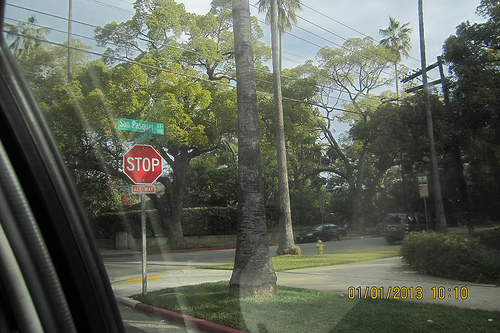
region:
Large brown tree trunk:
[210, 43, 274, 302]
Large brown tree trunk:
[415, 110, 453, 242]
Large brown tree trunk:
[335, 148, 364, 245]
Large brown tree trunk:
[267, 103, 302, 258]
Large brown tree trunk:
[161, 161, 196, 281]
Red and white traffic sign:
[118, 140, 159, 280]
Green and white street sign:
[103, 105, 178, 135]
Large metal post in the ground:
[122, 193, 152, 298]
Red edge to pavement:
[132, 297, 195, 328]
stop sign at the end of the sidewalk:
[111, 131, 172, 301]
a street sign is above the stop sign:
[112, 105, 167, 141]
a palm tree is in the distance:
[262, 1, 296, 252]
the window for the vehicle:
[27, 15, 474, 325]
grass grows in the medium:
[153, 279, 485, 329]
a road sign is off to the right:
[410, 168, 435, 226]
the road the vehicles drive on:
[103, 185, 477, 322]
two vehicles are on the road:
[293, 212, 434, 247]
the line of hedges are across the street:
[102, 202, 355, 243]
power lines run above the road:
[4, 0, 455, 130]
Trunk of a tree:
[271, 0, 299, 273]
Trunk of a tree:
[393, 47, 416, 247]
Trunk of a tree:
[350, 95, 376, 249]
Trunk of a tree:
[291, 136, 314, 232]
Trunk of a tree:
[169, 101, 202, 253]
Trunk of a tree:
[265, 5, 302, 264]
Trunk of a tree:
[288, 118, 317, 239]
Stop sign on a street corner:
[121, 143, 179, 315]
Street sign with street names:
[111, 107, 176, 182]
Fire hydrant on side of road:
[301, 225, 338, 263]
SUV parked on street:
[382, 173, 446, 263]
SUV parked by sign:
[384, 165, 443, 257]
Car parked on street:
[290, 214, 357, 247]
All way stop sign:
[113, 137, 172, 216]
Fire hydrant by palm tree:
[258, 0, 340, 267]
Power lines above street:
[301, 4, 462, 122]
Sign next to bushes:
[391, 169, 498, 288]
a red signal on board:
[78, 122, 210, 215]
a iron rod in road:
[124, 207, 151, 302]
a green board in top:
[112, 106, 174, 148]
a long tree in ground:
[210, 0, 284, 315]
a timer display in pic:
[337, 255, 496, 325]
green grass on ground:
[273, 273, 425, 326]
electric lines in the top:
[291, 34, 419, 104]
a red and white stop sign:
[120, 140, 165, 180]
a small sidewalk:
[272, 252, 498, 303]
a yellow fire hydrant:
[313, 239, 325, 253]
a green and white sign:
[114, 115, 167, 135]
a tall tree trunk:
[230, 0, 279, 294]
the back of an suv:
[377, 208, 431, 246]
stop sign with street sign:
[95, 105, 175, 307]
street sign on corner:
[115, 113, 164, 135]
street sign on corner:
[130, 127, 155, 145]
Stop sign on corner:
[121, 143, 162, 181]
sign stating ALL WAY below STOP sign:
[127, 182, 156, 196]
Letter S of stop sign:
[123, 155, 136, 175]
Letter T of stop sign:
[132, 155, 143, 174]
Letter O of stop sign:
[140, 154, 153, 172]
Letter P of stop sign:
[150, 155, 160, 172]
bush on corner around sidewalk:
[391, 226, 498, 283]